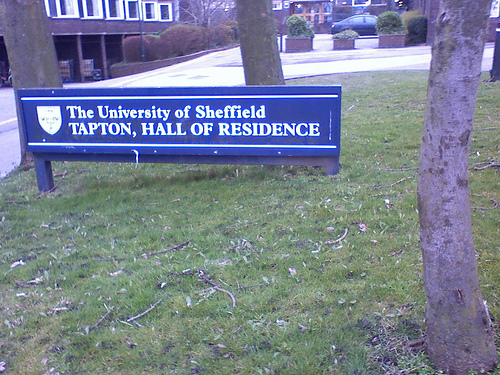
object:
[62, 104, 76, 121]
letter t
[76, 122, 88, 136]
letter a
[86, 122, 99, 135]
letter p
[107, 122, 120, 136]
letter o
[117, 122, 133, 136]
letter n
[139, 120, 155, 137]
letter h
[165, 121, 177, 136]
letter l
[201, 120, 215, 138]
letter f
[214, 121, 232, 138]
letter r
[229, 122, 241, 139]
letter e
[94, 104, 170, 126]
university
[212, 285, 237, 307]
stick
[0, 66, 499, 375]
lawn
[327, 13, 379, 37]
car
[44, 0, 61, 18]
window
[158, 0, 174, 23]
window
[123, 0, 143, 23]
window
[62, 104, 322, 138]
text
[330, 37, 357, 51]
pot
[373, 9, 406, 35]
hedge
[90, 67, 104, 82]
object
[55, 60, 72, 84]
fence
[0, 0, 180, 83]
building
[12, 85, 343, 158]
sign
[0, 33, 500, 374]
ground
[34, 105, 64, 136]
logo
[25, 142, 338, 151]
stripe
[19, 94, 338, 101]
stripe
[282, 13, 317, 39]
bush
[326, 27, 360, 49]
planter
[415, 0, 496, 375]
tree trunk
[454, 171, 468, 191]
mark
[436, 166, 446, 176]
mark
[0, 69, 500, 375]
grass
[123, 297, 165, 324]
branch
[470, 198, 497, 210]
branch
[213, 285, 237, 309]
branch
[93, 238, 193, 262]
branch